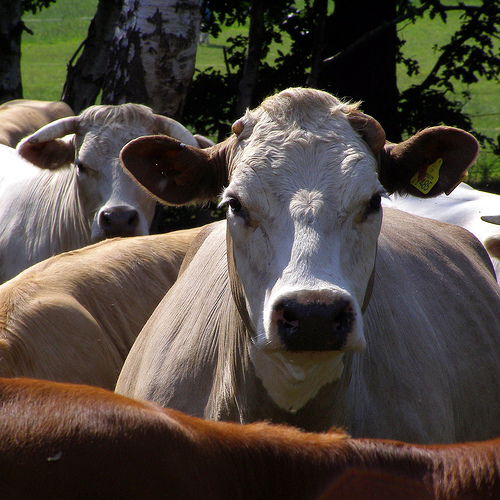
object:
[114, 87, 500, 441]
cow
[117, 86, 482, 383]
head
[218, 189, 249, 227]
eye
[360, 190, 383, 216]
eye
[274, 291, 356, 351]
nose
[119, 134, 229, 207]
ear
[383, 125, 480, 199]
ear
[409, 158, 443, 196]
tag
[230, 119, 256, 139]
horn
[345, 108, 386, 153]
horn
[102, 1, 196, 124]
trunk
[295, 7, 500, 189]
tree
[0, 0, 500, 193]
field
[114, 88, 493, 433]
fur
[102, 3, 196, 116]
bark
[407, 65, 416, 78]
leaf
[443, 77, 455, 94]
leaf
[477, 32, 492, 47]
leaf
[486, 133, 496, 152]
leaf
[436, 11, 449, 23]
leaf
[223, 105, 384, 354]
face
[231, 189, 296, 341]
shadow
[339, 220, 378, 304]
shadow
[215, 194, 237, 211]
lashes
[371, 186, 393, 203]
lashes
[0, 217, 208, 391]
cows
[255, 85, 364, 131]
hair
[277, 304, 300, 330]
nostril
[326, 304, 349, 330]
nostril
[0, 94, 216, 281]
cow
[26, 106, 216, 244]
head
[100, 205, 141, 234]
nose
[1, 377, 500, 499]
cow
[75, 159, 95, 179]
eye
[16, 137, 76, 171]
ear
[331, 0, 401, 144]
trunk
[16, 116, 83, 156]
horn